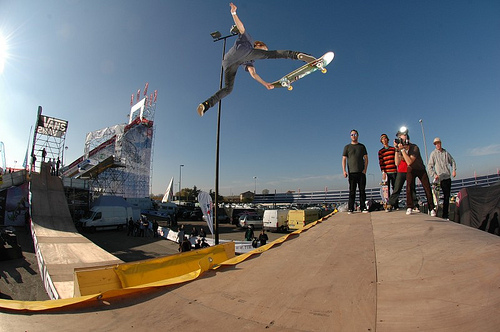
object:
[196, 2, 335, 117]
tricks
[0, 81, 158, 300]
skateboarding rink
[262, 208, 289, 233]
van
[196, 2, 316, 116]
man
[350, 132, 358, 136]
sunglasses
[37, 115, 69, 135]
sign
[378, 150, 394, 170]
striped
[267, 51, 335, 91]
skateboard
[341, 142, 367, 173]
shirt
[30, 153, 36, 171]
people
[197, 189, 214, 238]
flag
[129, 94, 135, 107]
flags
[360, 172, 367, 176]
pocket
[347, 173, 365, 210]
pants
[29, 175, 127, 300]
ramp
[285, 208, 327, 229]
cars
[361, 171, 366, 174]
hand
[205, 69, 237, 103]
leg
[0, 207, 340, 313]
tarp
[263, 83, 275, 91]
hand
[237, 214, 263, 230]
car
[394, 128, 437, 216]
boy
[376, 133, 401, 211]
boy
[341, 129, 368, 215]
boy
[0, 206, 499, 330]
skateboard landing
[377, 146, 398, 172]
shirt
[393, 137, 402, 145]
camera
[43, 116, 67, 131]
"vans"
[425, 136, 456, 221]
guy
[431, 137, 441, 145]
ballcap